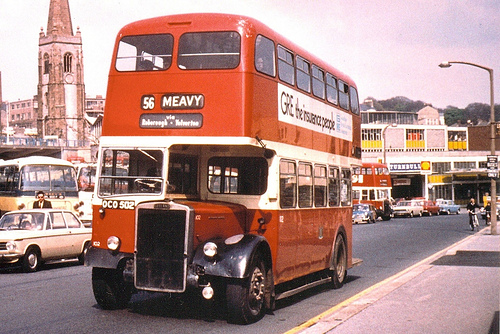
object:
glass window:
[248, 37, 277, 75]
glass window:
[276, 47, 294, 85]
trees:
[464, 100, 493, 123]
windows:
[348, 86, 361, 112]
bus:
[85, 12, 365, 324]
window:
[99, 150, 161, 193]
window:
[301, 160, 311, 207]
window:
[279, 163, 295, 207]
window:
[314, 164, 322, 205]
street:
[28, 182, 461, 332]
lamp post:
[451, 62, 496, 234]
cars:
[374, 200, 393, 220]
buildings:
[346, 99, 498, 204]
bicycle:
[465, 212, 480, 232]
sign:
[138, 112, 200, 127]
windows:
[164, 153, 200, 194]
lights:
[201, 285, 213, 298]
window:
[204, 156, 265, 194]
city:
[6, 4, 493, 333]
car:
[0, 208, 92, 273]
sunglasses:
[38, 194, 43, 198]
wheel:
[219, 246, 269, 322]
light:
[437, 63, 449, 68]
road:
[0, 208, 483, 331]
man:
[33, 192, 50, 208]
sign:
[484, 154, 499, 170]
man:
[466, 197, 475, 229]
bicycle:
[484, 210, 488, 223]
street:
[0, 207, 495, 331]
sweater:
[467, 204, 477, 212]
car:
[435, 200, 459, 214]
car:
[352, 202, 371, 223]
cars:
[391, 198, 423, 218]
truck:
[351, 157, 396, 218]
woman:
[200, 36, 221, 69]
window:
[170, 25, 245, 68]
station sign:
[430, 176, 445, 182]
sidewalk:
[290, 228, 496, 331]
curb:
[283, 233, 483, 332]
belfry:
[45, 52, 52, 75]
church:
[0, 0, 102, 154]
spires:
[65, 54, 72, 73]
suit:
[32, 201, 47, 209]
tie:
[38, 201, 44, 207]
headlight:
[201, 241, 216, 257]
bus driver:
[136, 153, 161, 193]